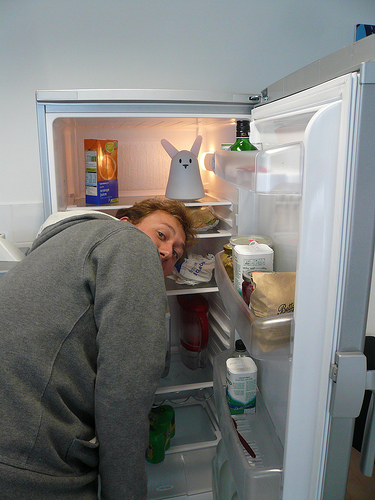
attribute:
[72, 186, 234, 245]
shelf — clear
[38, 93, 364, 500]
refrigerator — open, white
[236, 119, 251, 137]
bottle lid — black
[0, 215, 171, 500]
jacket — gray, grey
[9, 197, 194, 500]
man — leaning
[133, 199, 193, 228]
hair — blonde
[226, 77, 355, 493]
refrigerator door — white, open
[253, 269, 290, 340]
bag — paper, brown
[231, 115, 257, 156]
bottle — green, clear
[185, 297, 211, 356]
canister — red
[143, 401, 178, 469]
soda — pack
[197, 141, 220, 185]
light — on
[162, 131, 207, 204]
cat — rabbit shaped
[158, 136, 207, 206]
rabbit — white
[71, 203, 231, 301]
edge — white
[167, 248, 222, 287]
bag — plastic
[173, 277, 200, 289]
spoon — plastic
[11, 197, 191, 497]
boy — standing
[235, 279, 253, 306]
container — red